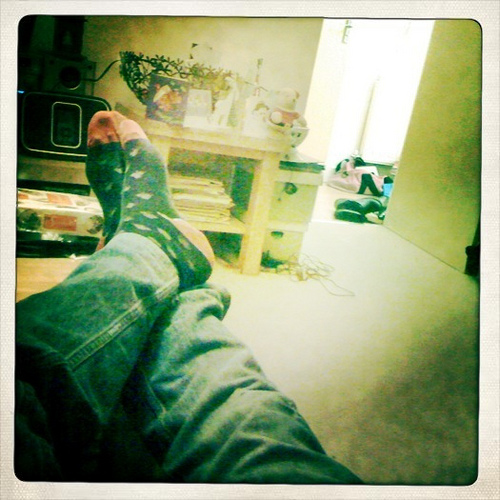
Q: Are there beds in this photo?
A: No, there are no beds.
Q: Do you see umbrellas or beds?
A: No, there are no beds or umbrellas.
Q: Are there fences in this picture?
A: No, there are no fences.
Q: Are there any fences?
A: No, there are no fences.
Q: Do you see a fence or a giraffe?
A: No, there are no fences or giraffes.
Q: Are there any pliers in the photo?
A: No, there are no pliers.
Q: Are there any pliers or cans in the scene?
A: No, there are no pliers or cans.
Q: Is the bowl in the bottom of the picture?
A: No, the bowl is in the top of the image.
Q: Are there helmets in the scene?
A: No, there are no helmets.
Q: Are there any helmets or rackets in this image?
A: No, there are no helmets or rackets.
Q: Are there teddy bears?
A: Yes, there is a teddy bear.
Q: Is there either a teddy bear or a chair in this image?
A: Yes, there is a teddy bear.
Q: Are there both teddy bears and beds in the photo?
A: No, there is a teddy bear but no beds.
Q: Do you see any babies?
A: No, there are no babies.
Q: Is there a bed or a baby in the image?
A: No, there are no babies or beds.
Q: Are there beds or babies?
A: No, there are no babies or beds.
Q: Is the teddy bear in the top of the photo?
A: Yes, the teddy bear is in the top of the image.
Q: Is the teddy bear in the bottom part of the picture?
A: No, the teddy bear is in the top of the image.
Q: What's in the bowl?
A: The teddy bear is in the bowl.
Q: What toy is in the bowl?
A: The toy is a teddy bear.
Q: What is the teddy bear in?
A: The teddy bear is in the bowl.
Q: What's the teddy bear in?
A: The teddy bear is in the bowl.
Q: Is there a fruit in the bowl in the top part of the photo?
A: No, there is a teddy bear in the bowl.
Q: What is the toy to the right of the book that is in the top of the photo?
A: The toy is a teddy bear.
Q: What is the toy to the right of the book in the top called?
A: The toy is a teddy bear.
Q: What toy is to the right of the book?
A: The toy is a teddy bear.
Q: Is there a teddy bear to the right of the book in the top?
A: Yes, there is a teddy bear to the right of the book.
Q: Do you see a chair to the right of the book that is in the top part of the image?
A: No, there is a teddy bear to the right of the book.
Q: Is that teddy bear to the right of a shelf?
A: No, the teddy bear is to the right of a book.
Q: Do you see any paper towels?
A: No, there are no paper towels.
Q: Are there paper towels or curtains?
A: No, there are no paper towels or curtains.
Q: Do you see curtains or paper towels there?
A: No, there are no paper towels or curtains.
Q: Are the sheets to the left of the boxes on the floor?
A: Yes, the sheets are to the left of the boxes.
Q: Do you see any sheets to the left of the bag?
A: Yes, there are sheets to the left of the bag.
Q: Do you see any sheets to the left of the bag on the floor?
A: Yes, there are sheets to the left of the bag.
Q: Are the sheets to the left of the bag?
A: Yes, the sheets are to the left of the bag.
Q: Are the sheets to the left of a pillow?
A: No, the sheets are to the left of the bag.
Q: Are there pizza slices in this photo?
A: No, there are no pizza slices.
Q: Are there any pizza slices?
A: No, there are no pizza slices.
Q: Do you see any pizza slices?
A: No, there are no pizza slices.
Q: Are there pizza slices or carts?
A: No, there are no pizza slices or carts.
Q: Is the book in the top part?
A: Yes, the book is in the top of the image.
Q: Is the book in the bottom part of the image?
A: No, the book is in the top of the image.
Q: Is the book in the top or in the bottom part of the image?
A: The book is in the top of the image.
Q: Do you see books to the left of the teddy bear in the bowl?
A: Yes, there is a book to the left of the teddy bear.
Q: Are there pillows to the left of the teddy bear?
A: No, there is a book to the left of the teddy bear.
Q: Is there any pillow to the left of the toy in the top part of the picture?
A: No, there is a book to the left of the teddy bear.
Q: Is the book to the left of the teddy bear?
A: Yes, the book is to the left of the teddy bear.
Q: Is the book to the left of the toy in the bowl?
A: Yes, the book is to the left of the teddy bear.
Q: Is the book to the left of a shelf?
A: No, the book is to the left of the teddy bear.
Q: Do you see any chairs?
A: No, there are no chairs.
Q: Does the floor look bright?
A: Yes, the floor is bright.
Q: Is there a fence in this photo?
A: No, there are no fences.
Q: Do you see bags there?
A: Yes, there is a bag.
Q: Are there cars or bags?
A: Yes, there is a bag.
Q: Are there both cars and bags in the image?
A: No, there is a bag but no cars.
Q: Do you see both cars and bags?
A: No, there is a bag but no cars.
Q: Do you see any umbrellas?
A: No, there are no umbrellas.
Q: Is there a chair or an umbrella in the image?
A: No, there are no umbrellas or chairs.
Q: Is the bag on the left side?
A: No, the bag is on the right of the image.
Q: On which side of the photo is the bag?
A: The bag is on the right of the image.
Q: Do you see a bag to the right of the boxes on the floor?
A: Yes, there is a bag to the right of the boxes.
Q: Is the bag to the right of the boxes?
A: Yes, the bag is to the right of the boxes.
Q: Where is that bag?
A: The bag is on the floor.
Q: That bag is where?
A: The bag is on the floor.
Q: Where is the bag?
A: The bag is on the floor.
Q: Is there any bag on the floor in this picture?
A: Yes, there is a bag on the floor.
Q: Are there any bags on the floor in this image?
A: Yes, there is a bag on the floor.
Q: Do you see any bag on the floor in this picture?
A: Yes, there is a bag on the floor.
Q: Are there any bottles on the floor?
A: No, there is a bag on the floor.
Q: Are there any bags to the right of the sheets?
A: Yes, there is a bag to the right of the sheets.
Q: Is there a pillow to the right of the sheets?
A: No, there is a bag to the right of the sheets.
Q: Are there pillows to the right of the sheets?
A: No, there is a bag to the right of the sheets.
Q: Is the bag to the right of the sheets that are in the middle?
A: Yes, the bag is to the right of the sheets.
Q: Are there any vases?
A: No, there are no vases.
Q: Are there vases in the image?
A: No, there are no vases.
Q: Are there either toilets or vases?
A: No, there are no vases or toilets.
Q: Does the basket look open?
A: Yes, the basket is open.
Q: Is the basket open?
A: Yes, the basket is open.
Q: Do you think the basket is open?
A: Yes, the basket is open.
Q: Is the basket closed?
A: No, the basket is open.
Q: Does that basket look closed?
A: No, the basket is open.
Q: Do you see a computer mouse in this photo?
A: No, there are no computer mice.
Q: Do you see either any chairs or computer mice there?
A: No, there are no computer mice or chairs.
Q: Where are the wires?
A: The wires are on the floor.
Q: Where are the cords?
A: The wires are on the floor.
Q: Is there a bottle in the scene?
A: No, there are no bottles.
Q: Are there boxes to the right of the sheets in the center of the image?
A: Yes, there are boxes to the right of the sheets.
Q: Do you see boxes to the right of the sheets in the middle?
A: Yes, there are boxes to the right of the sheets.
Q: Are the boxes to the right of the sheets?
A: Yes, the boxes are to the right of the sheets.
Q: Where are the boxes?
A: The boxes are on the floor.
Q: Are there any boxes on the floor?
A: Yes, there are boxes on the floor.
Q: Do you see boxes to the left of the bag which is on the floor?
A: Yes, there are boxes to the left of the bag.